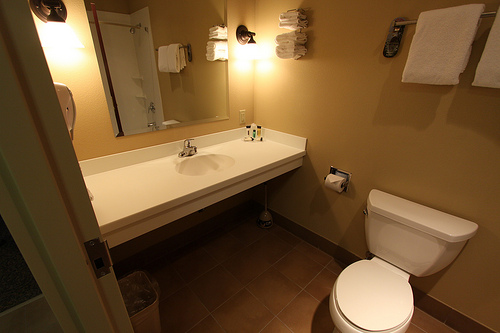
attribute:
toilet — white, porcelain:
[328, 187, 479, 332]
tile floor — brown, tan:
[117, 211, 462, 332]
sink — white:
[175, 151, 234, 175]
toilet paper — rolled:
[323, 174, 346, 194]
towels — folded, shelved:
[274, 8, 309, 60]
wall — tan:
[251, 0, 497, 332]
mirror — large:
[84, 1, 230, 137]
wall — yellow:
[29, 1, 255, 280]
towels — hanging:
[156, 41, 186, 75]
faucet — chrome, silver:
[177, 136, 198, 158]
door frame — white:
[1, 0, 137, 332]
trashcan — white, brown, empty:
[118, 266, 162, 331]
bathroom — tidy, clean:
[0, 0, 499, 332]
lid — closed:
[337, 258, 414, 333]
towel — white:
[400, 4, 485, 87]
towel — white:
[471, 6, 499, 90]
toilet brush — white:
[257, 180, 274, 229]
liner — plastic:
[116, 265, 161, 326]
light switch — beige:
[238, 109, 246, 126]